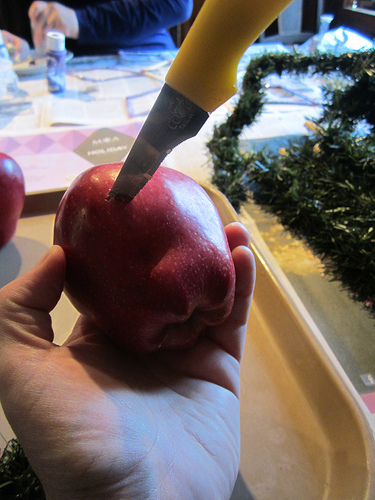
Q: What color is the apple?
A: Red.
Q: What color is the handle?
A: Yellow.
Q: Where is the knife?
A: In the apple.